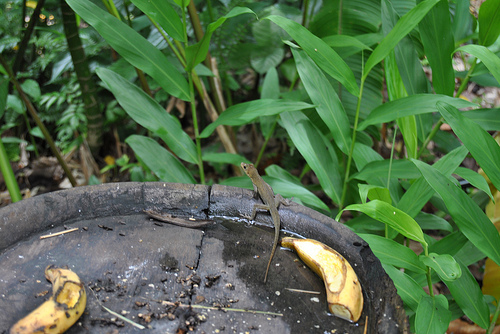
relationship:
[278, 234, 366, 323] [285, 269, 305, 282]
banana in water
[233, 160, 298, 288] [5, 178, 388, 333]
lizard on bird bath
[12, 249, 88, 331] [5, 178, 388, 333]
banana on bird bath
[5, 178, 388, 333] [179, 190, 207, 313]
bird bath has crack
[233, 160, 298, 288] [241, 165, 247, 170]
lizard has eye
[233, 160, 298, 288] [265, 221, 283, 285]
lizard has tail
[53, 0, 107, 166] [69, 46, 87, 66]
trunk has stripes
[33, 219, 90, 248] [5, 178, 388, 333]
stick on bird bath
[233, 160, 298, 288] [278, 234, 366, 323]
lizard beside banana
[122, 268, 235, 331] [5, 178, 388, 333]
pieces on bird bath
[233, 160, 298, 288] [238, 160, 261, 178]
lizard has head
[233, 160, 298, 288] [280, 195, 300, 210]
lizard has foot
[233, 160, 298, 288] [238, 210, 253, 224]
lizard has foot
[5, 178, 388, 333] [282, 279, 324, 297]
bird bath has stick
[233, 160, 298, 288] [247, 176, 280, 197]
lizard has arms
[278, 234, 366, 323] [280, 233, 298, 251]
banana has stem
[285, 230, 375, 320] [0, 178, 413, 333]
banana laying on bird bath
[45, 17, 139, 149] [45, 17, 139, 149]
trunk of plant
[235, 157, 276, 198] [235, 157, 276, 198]
eye of lizard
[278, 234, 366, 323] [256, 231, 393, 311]
banana on water